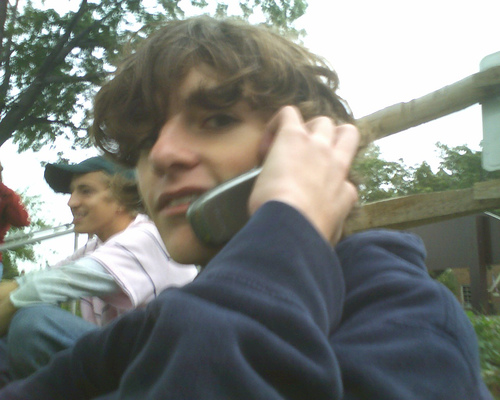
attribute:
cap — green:
[45, 153, 137, 194]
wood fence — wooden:
[310, 68, 499, 257]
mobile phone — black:
[182, 165, 275, 255]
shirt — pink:
[79, 230, 211, 312]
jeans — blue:
[0, 290, 114, 382]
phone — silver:
[184, 169, 263, 248]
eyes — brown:
[126, 107, 244, 151]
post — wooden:
[355, 64, 498, 154]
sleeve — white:
[9, 256, 121, 316]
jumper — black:
[127, 305, 471, 399]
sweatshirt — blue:
[90, 212, 475, 398]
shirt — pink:
[0, 152, 210, 383]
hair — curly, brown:
[81, 10, 371, 241]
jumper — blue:
[13, 223, 491, 395]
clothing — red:
[1, 175, 33, 255]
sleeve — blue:
[113, 203, 340, 399]